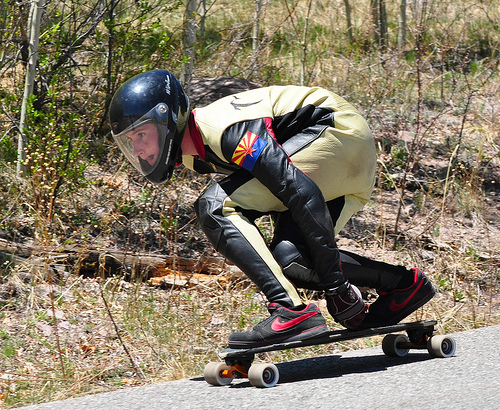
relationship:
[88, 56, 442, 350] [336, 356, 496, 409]
skateboarder on road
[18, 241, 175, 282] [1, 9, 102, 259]
log in woods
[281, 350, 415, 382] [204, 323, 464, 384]
shadow under skateboard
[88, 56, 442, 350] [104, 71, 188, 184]
woman wearing helmet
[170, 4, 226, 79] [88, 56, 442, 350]
tree behind woman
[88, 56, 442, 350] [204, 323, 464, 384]
woman riding skateboard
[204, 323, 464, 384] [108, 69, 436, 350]
skateboard under skateboarder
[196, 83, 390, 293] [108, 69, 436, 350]
suit on skateboarder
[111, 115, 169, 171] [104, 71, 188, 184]
shield on helmet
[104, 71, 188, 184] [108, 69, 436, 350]
helmet on skateboarder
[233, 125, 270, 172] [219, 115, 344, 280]
flag on arm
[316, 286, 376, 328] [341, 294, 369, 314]
glove on hand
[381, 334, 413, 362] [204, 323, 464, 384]
wheel on skateboard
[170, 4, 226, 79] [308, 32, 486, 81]
tree on hill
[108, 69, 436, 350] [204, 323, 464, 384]
skateboarder on skateboard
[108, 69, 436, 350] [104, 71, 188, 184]
skateboarder wearing helmet